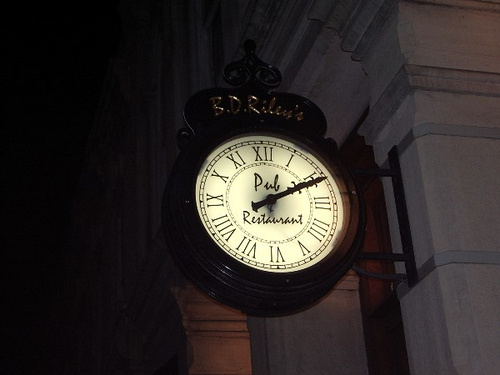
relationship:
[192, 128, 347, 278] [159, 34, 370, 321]
clock face belonging to clock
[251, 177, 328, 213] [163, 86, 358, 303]
clockhand belonging to clock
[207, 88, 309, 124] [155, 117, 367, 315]
gold lettering mounted on top of clock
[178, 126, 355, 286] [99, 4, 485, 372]
clock mounted on building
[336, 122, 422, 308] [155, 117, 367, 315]
mounting plate mounting clock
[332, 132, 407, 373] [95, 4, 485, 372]
door leading to pub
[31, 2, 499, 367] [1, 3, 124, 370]
building standing under sky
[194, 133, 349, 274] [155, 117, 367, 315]
face belonging to clock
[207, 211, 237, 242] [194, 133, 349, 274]
roman numeral painted on face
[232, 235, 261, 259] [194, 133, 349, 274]
roman numeral painted on face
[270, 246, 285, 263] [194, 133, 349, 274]
numeral painted on face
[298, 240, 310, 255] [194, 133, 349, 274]
roman painted on face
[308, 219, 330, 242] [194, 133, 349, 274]
roman numeral painted on face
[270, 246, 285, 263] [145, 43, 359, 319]
numeral painted on clock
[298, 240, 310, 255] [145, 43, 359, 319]
roman painted on clock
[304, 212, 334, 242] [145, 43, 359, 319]
roman numeral painted on clock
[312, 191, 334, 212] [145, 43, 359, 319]
roman numeral painted on clock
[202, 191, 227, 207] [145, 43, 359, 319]
roman numeral painted on clock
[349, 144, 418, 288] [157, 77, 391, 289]
bar mounting clock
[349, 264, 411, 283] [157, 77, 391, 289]
bar mounting clock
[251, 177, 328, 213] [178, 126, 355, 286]
clockhand belonging to clock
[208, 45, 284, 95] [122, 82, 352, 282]
decoration mounted on top of clock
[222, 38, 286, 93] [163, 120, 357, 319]
embellishment on top of clock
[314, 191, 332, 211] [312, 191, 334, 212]
letters making roman numeral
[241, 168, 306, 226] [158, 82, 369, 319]
script written on clock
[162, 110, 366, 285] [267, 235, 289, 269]
face with numerals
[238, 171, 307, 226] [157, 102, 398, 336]
text on clcok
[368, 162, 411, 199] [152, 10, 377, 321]
ground on top of clock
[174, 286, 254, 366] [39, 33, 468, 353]
light shining on building